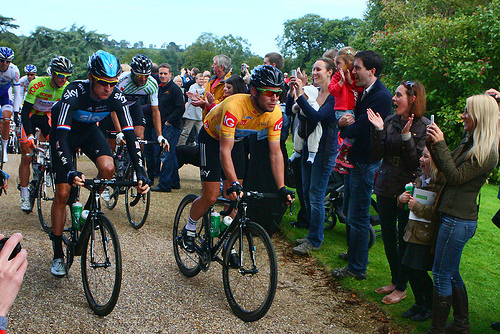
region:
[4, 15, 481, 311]
cyclists at a race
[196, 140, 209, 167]
white stripes on black shorts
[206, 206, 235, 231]
plastic green water bottles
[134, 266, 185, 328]
brown gravel on the ground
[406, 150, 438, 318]
a little girl holding a notebook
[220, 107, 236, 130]
a red and white logo on a sleeve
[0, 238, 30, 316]
a hand holding a camera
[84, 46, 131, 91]
a blue and turquoise helmey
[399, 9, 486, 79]
trees behind the crowd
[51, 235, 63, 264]
a black sock on a foot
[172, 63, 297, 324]
man in yellow top riding a bicycle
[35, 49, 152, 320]
man wearing blue helmet riding a bike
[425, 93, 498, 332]
woman with long blonde hair taking a picture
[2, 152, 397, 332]
road the bikers are on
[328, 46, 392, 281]
man holding a clapping child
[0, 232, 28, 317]
hand holding black phone on the left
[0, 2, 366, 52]
sky above the people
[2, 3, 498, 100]
green trees in the background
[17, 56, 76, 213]
man in lime green top riding a bike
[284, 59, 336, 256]
woman with baby strapped to chest taking a photo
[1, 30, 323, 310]
Men riding bikes on a gravel road.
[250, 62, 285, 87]
The man is wearing a bike helmet.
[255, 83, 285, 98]
The man is wearing green sunglasses.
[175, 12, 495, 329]
Spectators along the side of the road.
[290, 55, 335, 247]
An infant in a baby sling attached to the woman.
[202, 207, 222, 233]
A green water bottle attached to the bike.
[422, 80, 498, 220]
A woman taking a picture with her cell phone.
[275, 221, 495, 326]
People standing on green grass.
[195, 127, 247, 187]
The man is wearing black and white shorts.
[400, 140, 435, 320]
The child is holding a book and a bottle.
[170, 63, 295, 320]
Man wearing black helmet riding bicycle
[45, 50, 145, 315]
Man wearing teal and black helmet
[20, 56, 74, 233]
Man wearing orange and black shorts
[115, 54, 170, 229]
Man wearing white and green shirt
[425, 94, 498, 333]
Man taking a picture with phone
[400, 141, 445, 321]
Girl standing and laughing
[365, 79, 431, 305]
Woman standing and watching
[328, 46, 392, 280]
Man standing and holding little girl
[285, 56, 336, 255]
Woman standing and looking at phone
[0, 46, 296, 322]
Six men in a bicycle race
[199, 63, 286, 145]
Man wearing a yellow shirt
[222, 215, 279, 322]
Black wheel of a bicycle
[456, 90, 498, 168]
Woman with blond hair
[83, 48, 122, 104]
Man with a cycling helmet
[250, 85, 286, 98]
Green framed sunglasses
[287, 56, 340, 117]
Woman holding a camera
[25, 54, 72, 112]
Man wearing a neon green shirt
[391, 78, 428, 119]
Woman with light brown hair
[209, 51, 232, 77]
Man with gray hair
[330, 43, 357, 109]
Young girl with red shirt